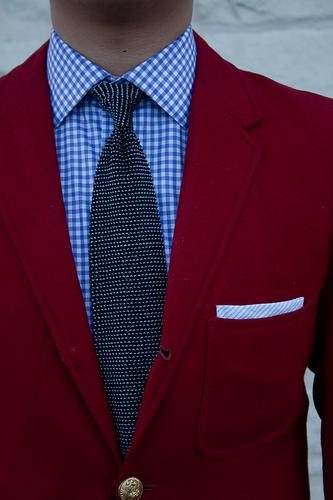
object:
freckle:
[122, 49, 127, 54]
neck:
[51, 0, 196, 70]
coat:
[0, 354, 63, 500]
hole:
[142, 485, 160, 492]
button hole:
[158, 346, 174, 366]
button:
[116, 472, 148, 498]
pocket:
[195, 291, 307, 459]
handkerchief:
[215, 297, 304, 319]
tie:
[86, 76, 174, 457]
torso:
[0, 30, 333, 499]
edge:
[147, 178, 155, 200]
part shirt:
[61, 119, 85, 185]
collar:
[44, 26, 197, 126]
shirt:
[43, 29, 199, 334]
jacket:
[0, 23, 333, 498]